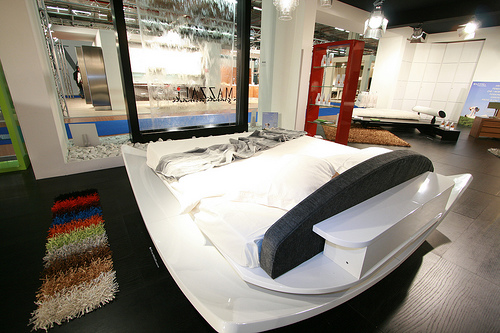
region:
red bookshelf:
[304, 34, 366, 144]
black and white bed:
[115, 120, 489, 325]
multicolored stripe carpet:
[30, 173, 124, 326]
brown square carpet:
[321, 120, 418, 151]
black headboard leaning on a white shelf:
[246, 135, 453, 278]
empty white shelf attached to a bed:
[310, 166, 458, 284]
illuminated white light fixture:
[455, 15, 485, 45]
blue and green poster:
[456, 71, 497, 141]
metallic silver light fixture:
[402, 20, 429, 50]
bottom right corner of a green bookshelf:
[0, 54, 35, 189]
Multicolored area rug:
[30, 194, 116, 323]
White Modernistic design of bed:
[142, 141, 383, 302]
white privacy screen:
[377, 53, 479, 91]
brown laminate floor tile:
[402, 249, 490, 317]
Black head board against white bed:
[263, 148, 436, 272]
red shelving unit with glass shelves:
[298, 36, 369, 130]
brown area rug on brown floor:
[322, 121, 408, 150]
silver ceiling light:
[352, 8, 395, 42]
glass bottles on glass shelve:
[309, 88, 342, 112]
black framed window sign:
[111, 10, 260, 142]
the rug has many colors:
[25, 173, 141, 331]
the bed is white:
[140, 100, 412, 255]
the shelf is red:
[309, 27, 365, 149]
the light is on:
[448, 12, 482, 47]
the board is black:
[232, 141, 447, 275]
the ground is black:
[110, 211, 146, 286]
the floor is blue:
[97, 114, 130, 131]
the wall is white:
[20, 62, 55, 144]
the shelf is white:
[298, 165, 470, 264]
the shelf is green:
[0, 61, 32, 181]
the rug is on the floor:
[25, 175, 129, 330]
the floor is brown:
[438, 256, 483, 310]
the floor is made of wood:
[432, 256, 491, 306]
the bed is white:
[199, 166, 326, 221]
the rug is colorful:
[37, 165, 129, 325]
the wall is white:
[480, 51, 497, 59]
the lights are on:
[278, 5, 487, 59]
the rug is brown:
[312, 120, 445, 151]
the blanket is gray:
[156, 109, 353, 176]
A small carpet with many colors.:
[29, 178, 118, 330]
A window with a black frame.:
[109, 0, 249, 147]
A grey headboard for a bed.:
[245, 142, 451, 290]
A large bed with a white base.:
[112, 123, 474, 328]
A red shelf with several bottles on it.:
[288, 30, 364, 150]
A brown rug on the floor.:
[322, 116, 409, 151]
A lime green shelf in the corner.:
[0, 67, 38, 180]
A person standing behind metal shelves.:
[67, 54, 87, 105]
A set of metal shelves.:
[79, 38, 105, 113]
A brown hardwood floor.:
[2, 100, 498, 329]